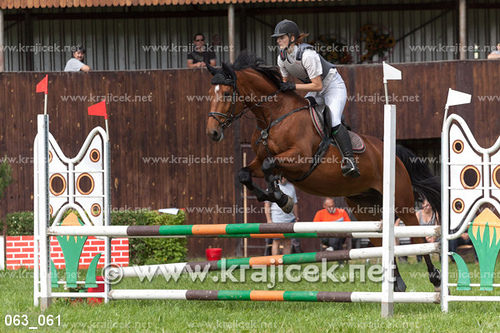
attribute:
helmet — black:
[271, 17, 301, 39]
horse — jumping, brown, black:
[202, 57, 441, 293]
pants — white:
[325, 65, 348, 121]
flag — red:
[85, 95, 110, 118]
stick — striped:
[50, 220, 383, 237]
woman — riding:
[271, 18, 360, 178]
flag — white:
[446, 89, 473, 107]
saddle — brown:
[307, 102, 367, 154]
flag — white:
[383, 59, 402, 84]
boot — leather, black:
[331, 123, 360, 173]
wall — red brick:
[7, 233, 131, 273]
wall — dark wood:
[3, 0, 251, 12]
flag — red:
[37, 76, 51, 93]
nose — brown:
[208, 126, 222, 146]